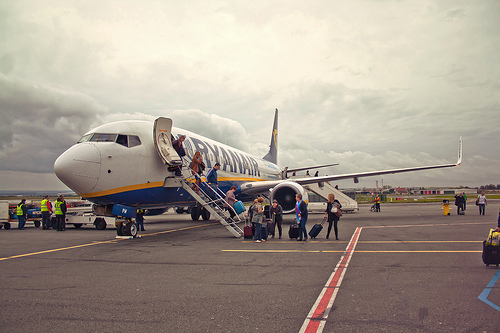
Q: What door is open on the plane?
A: Front and back.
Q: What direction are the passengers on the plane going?
A: Down stairs.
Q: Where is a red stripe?
A: On the tarmac.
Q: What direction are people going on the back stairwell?
A: Down.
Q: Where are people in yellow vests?
A: On ground on the left.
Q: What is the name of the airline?
A: Ryanair.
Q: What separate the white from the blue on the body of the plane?
A: Yellow stripe.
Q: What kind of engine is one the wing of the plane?
A: Jet.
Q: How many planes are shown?
A: One.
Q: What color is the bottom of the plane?
A: Blue.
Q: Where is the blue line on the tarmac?
A: Right side of the picture.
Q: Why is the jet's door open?
A: To allow passenger to exit.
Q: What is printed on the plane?
A: Ryanair.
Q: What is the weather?
A: Overcast.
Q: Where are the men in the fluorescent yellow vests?
A: Left of the plane.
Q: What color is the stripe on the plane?
A: Yellow.